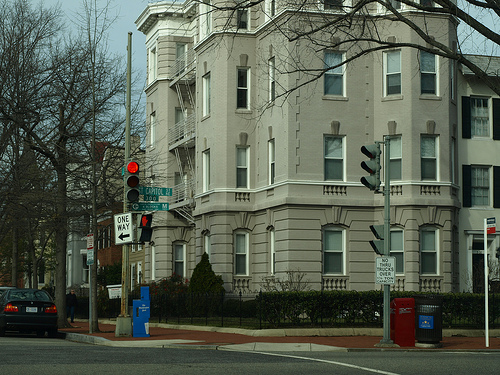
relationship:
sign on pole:
[112, 211, 137, 246] [115, 29, 132, 341]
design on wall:
[128, 0, 201, 30] [131, 1, 491, 292]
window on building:
[323, 222, 344, 274] [118, 0, 498, 321]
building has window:
[118, 0, 498, 321] [384, 132, 404, 183]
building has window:
[118, 0, 498, 321] [471, 166, 493, 212]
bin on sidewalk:
[416, 294, 444, 344] [64, 320, 499, 356]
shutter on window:
[461, 163, 474, 206] [472, 162, 489, 208]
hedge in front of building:
[252, 290, 499, 329] [118, 0, 498, 321]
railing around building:
[70, 288, 499, 331] [118, 0, 498, 321]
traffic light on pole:
[122, 154, 143, 210] [119, 28, 168, 271]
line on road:
[277, 346, 397, 373] [0, 338, 500, 373]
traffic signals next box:
[357, 124, 395, 340] [390, 297, 414, 350]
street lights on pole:
[357, 134, 389, 254] [379, 130, 397, 340]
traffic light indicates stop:
[122, 154, 143, 210] [122, 157, 140, 177]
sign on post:
[112, 211, 137, 246] [122, 126, 134, 329]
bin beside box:
[413, 295, 444, 346] [390, 297, 414, 350]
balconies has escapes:
[170, 32, 202, 217] [164, 35, 196, 271]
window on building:
[306, 124, 349, 181] [132, 18, 473, 295]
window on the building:
[318, 46, 349, 102] [188, 16, 454, 297]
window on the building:
[313, 49, 349, 105] [208, 25, 455, 286]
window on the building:
[318, 46, 349, 102] [175, 24, 456, 274]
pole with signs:
[102, 132, 132, 326] [93, 185, 172, 240]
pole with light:
[102, 132, 132, 326] [122, 148, 141, 210]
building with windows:
[135, 0, 498, 302] [172, 127, 447, 194]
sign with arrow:
[107, 203, 140, 247] [108, 227, 128, 240]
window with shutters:
[458, 88, 483, 133] [462, 100, 474, 140]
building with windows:
[135, 0, 498, 302] [196, 133, 444, 176]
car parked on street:
[6, 278, 56, 334] [37, 340, 86, 363]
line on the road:
[244, 346, 397, 373] [216, 348, 246, 370]